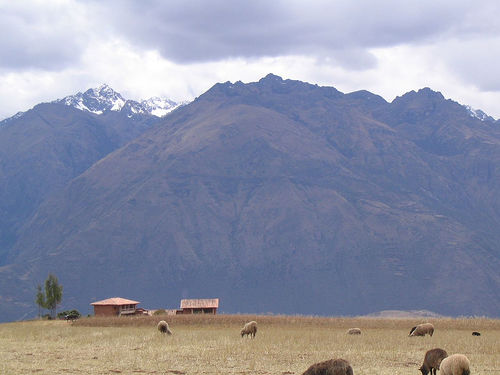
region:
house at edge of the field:
[87, 295, 137, 319]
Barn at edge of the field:
[181, 297, 219, 309]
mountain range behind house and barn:
[8, 72, 489, 314]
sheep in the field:
[157, 313, 497, 373]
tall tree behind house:
[38, 272, 62, 322]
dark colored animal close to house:
[63, 311, 79, 321]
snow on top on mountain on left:
[6, 77, 198, 119]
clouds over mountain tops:
[3, 3, 498, 86]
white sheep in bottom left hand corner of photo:
[437, 351, 472, 373]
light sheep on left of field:
[155, 320, 174, 334]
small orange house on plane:
[89, 295, 139, 322]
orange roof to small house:
[173, 295, 226, 313]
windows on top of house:
[120, 305, 134, 307]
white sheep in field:
[150, 317, 177, 335]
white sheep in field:
[233, 319, 265, 338]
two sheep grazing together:
[408, 345, 471, 372]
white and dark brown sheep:
[406, 343, 474, 374]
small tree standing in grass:
[32, 272, 78, 337]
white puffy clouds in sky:
[231, 0, 423, 87]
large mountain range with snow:
[0, 80, 374, 227]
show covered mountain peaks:
[48, 78, 184, 127]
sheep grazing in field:
[148, 314, 475, 374]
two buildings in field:
[87, 288, 227, 321]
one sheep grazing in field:
[235, 319, 265, 339]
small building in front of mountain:
[166, 70, 368, 321]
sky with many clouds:
[11, 3, 489, 74]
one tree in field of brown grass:
[33, 271, 66, 323]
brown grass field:
[70, 316, 144, 370]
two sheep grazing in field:
[156, 315, 260, 345]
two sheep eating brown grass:
[151, 316, 263, 348]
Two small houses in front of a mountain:
[87, 290, 233, 324]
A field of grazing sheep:
[142, 318, 499, 373]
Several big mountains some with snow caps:
[1, 61, 499, 326]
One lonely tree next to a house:
[28, 270, 69, 325]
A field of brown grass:
[0, 308, 499, 373]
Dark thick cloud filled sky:
[0, 0, 498, 132]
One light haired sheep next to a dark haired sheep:
[416, 345, 474, 373]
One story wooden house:
[88, 294, 142, 318]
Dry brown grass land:
[0, 305, 499, 374]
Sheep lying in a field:
[343, 325, 366, 337]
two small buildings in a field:
[80, 285, 222, 326]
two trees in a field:
[22, 259, 76, 326]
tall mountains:
[6, 81, 466, 268]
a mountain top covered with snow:
[60, 79, 197, 134]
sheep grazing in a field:
[141, 301, 483, 373]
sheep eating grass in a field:
[63, 294, 495, 373]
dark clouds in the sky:
[202, 15, 424, 60]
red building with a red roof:
[102, 279, 137, 327]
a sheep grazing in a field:
[403, 317, 440, 347]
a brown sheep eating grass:
[418, 344, 454, 373]